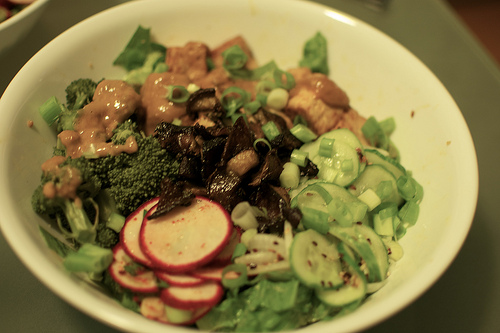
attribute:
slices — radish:
[110, 198, 243, 312]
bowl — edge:
[0, 0, 52, 46]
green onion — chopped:
[219, 41, 246, 71]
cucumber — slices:
[289, 229, 343, 289]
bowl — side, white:
[0, 3, 481, 330]